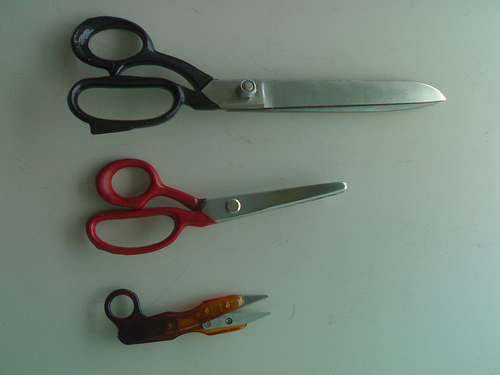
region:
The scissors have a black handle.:
[81, 14, 223, 138]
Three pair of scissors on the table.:
[59, 22, 407, 348]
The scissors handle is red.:
[81, 164, 206, 256]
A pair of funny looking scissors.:
[98, 272, 277, 345]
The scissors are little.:
[44, 288, 336, 355]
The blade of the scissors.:
[273, 48, 463, 132]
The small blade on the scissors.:
[238, 286, 268, 330]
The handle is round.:
[70, 291, 152, 321]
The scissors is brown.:
[100, 287, 232, 340]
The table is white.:
[296, 209, 471, 337]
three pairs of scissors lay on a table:
[56, 6, 453, 350]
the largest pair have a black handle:
[49, 15, 448, 138]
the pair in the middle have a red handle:
[78, 146, 353, 258]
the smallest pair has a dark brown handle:
[86, 273, 283, 355]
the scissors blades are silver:
[222, 72, 447, 122]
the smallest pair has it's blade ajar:
[183, 289, 282, 338]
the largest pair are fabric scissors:
[61, 10, 452, 137]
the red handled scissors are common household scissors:
[75, 150, 350, 260]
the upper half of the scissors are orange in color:
[183, 290, 266, 352]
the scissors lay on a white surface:
[7, 3, 488, 370]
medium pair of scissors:
[83, 153, 350, 257]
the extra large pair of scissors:
[63, 13, 448, 138]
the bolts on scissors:
[158, 70, 259, 341]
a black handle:
[63, 7, 224, 139]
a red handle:
[84, 154, 218, 259]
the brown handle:
[101, 284, 178, 345]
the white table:
[2, 2, 498, 374]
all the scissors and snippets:
[67, 12, 448, 348]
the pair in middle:
[83, 153, 350, 259]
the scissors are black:
[62, 19, 152, 71]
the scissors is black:
[64, 74, 179, 124]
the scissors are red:
[85, 148, 166, 206]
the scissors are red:
[65, 207, 157, 255]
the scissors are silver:
[255, 71, 441, 103]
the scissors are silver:
[359, 105, 406, 120]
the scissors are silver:
[247, 185, 264, 210]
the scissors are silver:
[282, 203, 302, 210]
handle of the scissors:
[37, 0, 200, 137]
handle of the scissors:
[60, 145, 197, 261]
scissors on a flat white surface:
[7, 10, 492, 362]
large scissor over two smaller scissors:
[56, 12, 448, 348]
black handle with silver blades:
[63, 15, 448, 135]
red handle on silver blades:
[83, 155, 350, 257]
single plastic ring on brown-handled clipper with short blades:
[92, 283, 273, 346]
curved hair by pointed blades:
[105, 285, 301, 330]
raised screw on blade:
[230, 72, 262, 104]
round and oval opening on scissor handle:
[60, 10, 205, 131]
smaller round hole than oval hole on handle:
[70, 155, 210, 255]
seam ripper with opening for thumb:
[87, 282, 273, 344]